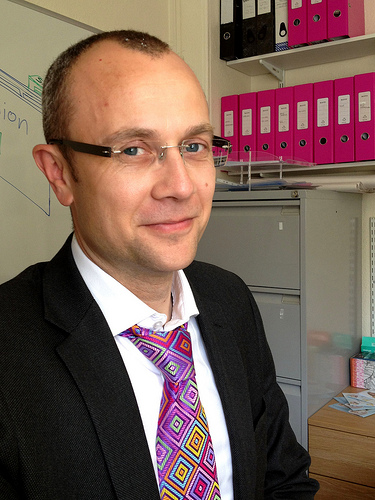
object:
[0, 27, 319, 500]
man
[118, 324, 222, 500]
tie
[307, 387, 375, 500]
table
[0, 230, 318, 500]
coat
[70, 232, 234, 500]
shirt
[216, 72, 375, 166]
files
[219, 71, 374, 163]
color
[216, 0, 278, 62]
color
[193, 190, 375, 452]
cupboard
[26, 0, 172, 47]
wall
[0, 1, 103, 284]
board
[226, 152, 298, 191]
racks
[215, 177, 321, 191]
files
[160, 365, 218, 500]
color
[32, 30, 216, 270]
head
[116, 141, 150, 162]
eye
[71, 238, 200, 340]
collar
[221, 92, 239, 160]
binder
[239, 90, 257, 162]
binder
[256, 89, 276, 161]
binder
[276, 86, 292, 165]
binder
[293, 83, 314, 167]
binder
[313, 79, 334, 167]
binder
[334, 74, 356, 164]
binder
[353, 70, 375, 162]
binder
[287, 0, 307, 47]
binder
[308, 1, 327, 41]
binder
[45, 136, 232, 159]
frame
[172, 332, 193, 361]
color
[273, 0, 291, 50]
file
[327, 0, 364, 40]
file